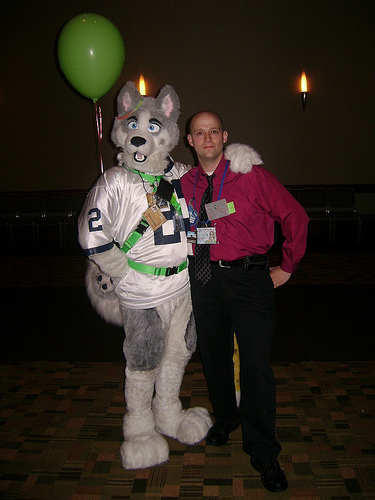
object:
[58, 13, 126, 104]
balloon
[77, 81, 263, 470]
person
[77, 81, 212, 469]
costume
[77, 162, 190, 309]
jersey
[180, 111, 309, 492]
man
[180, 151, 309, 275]
shirt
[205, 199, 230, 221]
sticker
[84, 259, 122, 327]
tail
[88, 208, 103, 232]
number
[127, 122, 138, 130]
eyes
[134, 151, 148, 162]
mouth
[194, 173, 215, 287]
tie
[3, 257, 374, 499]
floor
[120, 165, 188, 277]
straps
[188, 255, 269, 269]
belt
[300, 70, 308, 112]
light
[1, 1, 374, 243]
wall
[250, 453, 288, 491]
feet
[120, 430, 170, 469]
paws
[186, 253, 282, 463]
pants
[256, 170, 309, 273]
arms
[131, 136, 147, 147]
nose